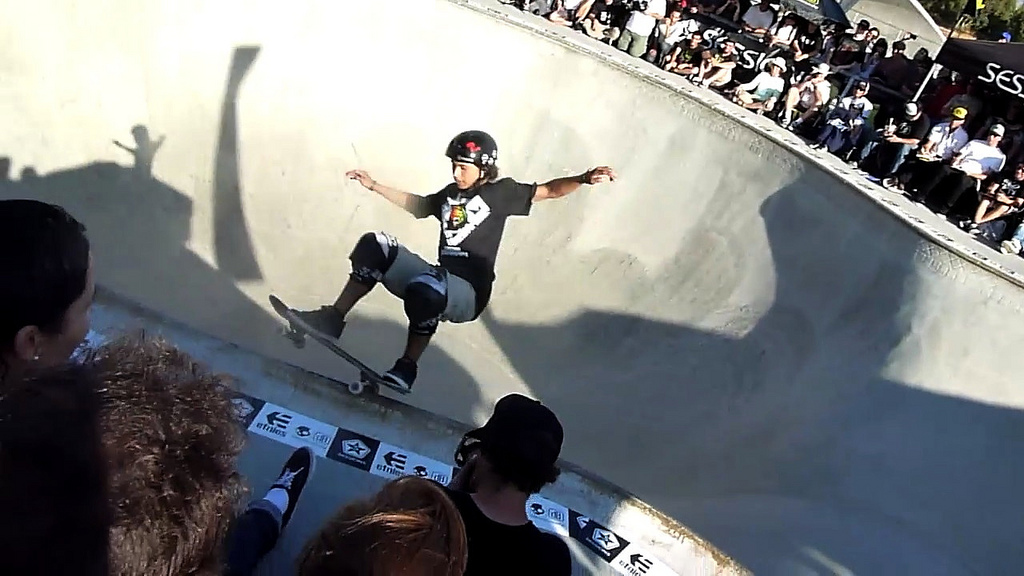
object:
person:
[740, 4, 780, 41]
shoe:
[380, 354, 419, 391]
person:
[0, 341, 264, 575]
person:
[829, 18, 868, 91]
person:
[779, 63, 832, 131]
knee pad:
[348, 231, 400, 290]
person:
[301, 473, 476, 574]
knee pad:
[402, 266, 447, 335]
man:
[284, 132, 610, 394]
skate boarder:
[268, 289, 415, 397]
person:
[430, 388, 574, 575]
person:
[877, 37, 915, 98]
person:
[888, 107, 967, 194]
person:
[919, 118, 1006, 219]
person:
[0, 192, 97, 380]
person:
[736, 55, 789, 116]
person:
[811, 81, 876, 152]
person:
[852, 98, 932, 181]